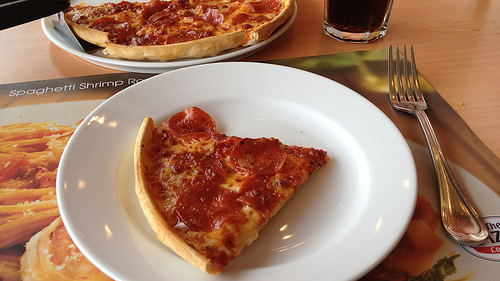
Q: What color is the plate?
A: White.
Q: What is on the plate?
A: Pizza.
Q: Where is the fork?
A: Right side of plate.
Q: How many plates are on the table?
A: Two.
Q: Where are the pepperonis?
A: Pizza.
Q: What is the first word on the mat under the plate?
A: Spaghetti.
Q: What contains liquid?
A: Glass.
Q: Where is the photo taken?
A: At a diner.